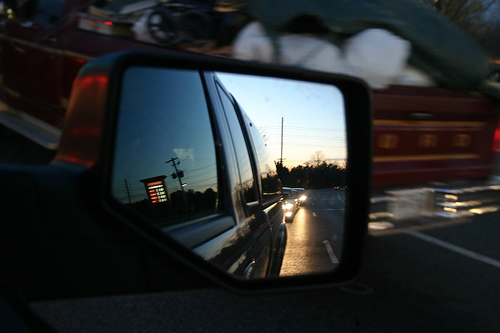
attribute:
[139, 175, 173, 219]
gas station — reflecting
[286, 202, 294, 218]
headlights — on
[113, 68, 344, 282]
mirror — reflecting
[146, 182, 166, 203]
sign — red, lit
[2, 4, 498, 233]
truck — maroon, loaded, red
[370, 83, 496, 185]
tailgate — red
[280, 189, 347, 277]
road — paved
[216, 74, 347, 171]
sky — clear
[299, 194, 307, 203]
headlights — on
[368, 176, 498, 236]
bumper — chrome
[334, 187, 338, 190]
red light — on, distant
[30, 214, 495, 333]
road — gray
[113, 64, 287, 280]
car — suv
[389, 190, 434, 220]
license plate — blurry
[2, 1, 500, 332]
background — blurry